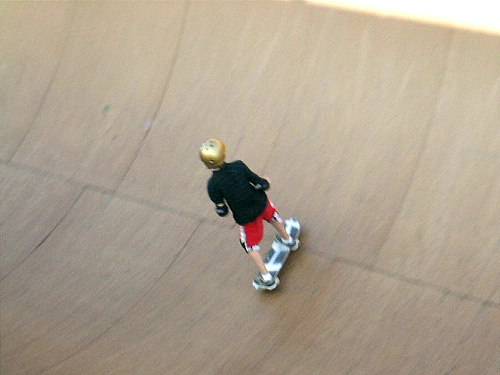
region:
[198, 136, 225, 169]
the helmet is gold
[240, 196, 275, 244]
the shorts are red and white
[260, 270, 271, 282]
the top of a white sock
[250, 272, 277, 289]
the shoe on the foot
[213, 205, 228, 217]
the black elbow pad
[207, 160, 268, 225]
the shirt on the boy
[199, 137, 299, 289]
the boy on the skateboard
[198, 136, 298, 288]
the boy is skateboarding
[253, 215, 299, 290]
the skateboard on the ramp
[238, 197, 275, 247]
the shorts on the boy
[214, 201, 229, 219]
the elbow pad on the boy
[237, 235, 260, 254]
the knee pad on the boy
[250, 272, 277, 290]
the shoe on the boy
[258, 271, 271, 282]
the top of the boy's sock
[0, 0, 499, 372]
the large ramp under the boy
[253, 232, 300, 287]
the shoes on the boy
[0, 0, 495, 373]
the lines on the ramp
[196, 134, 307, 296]
boy on white skateboard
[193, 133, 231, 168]
gold helmet on boy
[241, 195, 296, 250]
boy wearing red shorts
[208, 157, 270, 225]
boy wearing black shirt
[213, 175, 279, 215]
boy wearing black gloves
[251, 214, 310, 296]
black and white skateboard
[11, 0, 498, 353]
large concrete skate ramp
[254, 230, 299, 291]
white socks and grey sneakers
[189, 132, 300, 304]
young boy on skateboard on ramp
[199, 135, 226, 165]
gold hard helmet on boy's head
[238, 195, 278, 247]
the red and white shorts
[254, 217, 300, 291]
the skateboard under the boy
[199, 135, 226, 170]
the head of the boy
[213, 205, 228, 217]
the elbow pad on the boy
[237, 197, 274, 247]
the white on the shorts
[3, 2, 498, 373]
surface of skate ramp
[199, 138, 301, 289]
boy standing on skateboard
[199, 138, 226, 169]
top of gold helmet